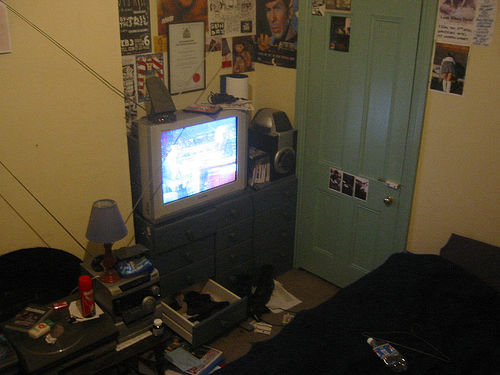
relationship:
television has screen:
[134, 112, 260, 208] [154, 129, 243, 188]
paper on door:
[322, 18, 354, 53] [295, 5, 415, 280]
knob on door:
[376, 196, 399, 213] [295, 5, 415, 280]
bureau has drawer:
[144, 207, 319, 331] [156, 290, 275, 335]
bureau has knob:
[144, 207, 319, 331] [182, 227, 201, 248]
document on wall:
[167, 20, 209, 95] [6, 4, 296, 205]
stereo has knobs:
[79, 258, 174, 334] [140, 298, 165, 315]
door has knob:
[295, 5, 415, 280] [376, 196, 399, 213]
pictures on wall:
[117, 3, 308, 102] [6, 4, 296, 205]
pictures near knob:
[325, 171, 379, 205] [376, 196, 399, 213]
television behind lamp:
[134, 112, 260, 208] [75, 205, 127, 268]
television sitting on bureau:
[134, 112, 260, 208] [144, 207, 319, 331]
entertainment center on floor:
[5, 276, 180, 374] [149, 263, 336, 357]